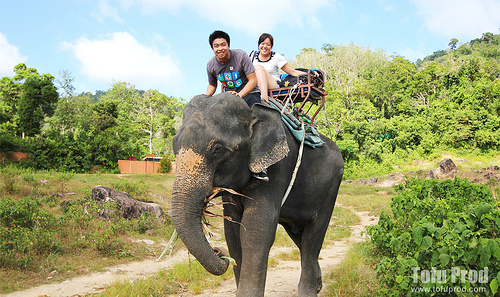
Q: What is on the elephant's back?
A: 2 people.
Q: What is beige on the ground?
A: Dirt path.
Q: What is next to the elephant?
A: Green bush.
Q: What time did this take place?
A: Afternoon.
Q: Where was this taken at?
A: Is outside.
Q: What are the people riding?
A: Elephant.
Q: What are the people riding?
A: Gray elephant.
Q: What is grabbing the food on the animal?
A: Brown trunk.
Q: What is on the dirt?
A: People on elephant.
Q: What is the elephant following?
A: Path of dirt.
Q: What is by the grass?
A: Dirt road.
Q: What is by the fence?
A: Tree with leaves.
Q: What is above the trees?
A: Blue sky.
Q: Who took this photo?
A: A professional.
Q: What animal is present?
A: Elephant.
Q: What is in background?
A: Thick forest.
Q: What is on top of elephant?
A: Two people.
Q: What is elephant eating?
A: Hay.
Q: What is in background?
A: House.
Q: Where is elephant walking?
A: Rocky trail.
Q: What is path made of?
A: Dirt.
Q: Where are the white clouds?
A: In the sky.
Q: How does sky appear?
A: Blue skies and clouds.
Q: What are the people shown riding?
A: An elephant.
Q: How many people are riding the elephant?
A: Two.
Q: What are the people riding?
A: An elephant.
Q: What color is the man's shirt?
A: Purple.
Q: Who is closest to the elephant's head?
A: A man.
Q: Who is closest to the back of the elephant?
A: A woman.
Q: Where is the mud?
A: On the elephant's trunk.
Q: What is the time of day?
A: Daytime.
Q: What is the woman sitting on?
A: A small bench.